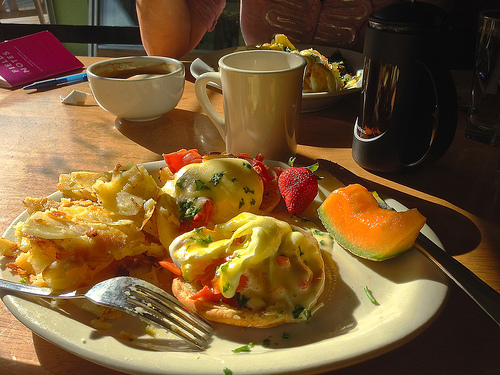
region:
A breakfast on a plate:
[19, 129, 439, 344]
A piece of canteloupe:
[321, 184, 429, 259]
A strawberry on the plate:
[277, 161, 319, 216]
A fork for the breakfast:
[9, 269, 214, 356]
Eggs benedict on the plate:
[177, 225, 339, 330]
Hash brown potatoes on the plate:
[20, 164, 161, 269]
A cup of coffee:
[197, 40, 312, 154]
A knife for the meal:
[391, 165, 498, 297]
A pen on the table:
[24, 63, 86, 90]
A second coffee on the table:
[79, 33, 189, 127]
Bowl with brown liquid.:
[89, 51, 191, 133]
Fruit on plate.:
[261, 163, 422, 270]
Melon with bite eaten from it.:
[344, 178, 417, 238]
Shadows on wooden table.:
[7, 84, 171, 207]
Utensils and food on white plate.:
[1, 154, 498, 333]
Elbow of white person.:
[135, 3, 218, 69]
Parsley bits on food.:
[177, 167, 280, 224]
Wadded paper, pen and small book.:
[2, 41, 96, 119]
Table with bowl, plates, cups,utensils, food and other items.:
[0, 45, 490, 370]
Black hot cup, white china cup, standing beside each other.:
[202, 49, 467, 188]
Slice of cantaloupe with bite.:
[319, 183, 416, 268]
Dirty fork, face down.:
[4, 269, 231, 367]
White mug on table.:
[196, 46, 323, 162]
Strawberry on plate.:
[278, 163, 325, 222]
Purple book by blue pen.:
[0, 29, 92, 97]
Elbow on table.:
[136, 1, 233, 70]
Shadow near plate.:
[1, 306, 136, 373]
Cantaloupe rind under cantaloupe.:
[319, 232, 406, 267]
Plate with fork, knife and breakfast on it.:
[12, 155, 432, 368]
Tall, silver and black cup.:
[345, 14, 453, 174]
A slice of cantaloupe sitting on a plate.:
[316, 167, 426, 261]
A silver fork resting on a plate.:
[0, 275, 216, 353]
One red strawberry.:
[276, 155, 326, 217]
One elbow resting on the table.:
[126, 17, 200, 64]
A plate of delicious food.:
[3, 142, 450, 367]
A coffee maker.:
[358, 10, 478, 196]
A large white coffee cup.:
[194, 48, 314, 163]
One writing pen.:
[15, 75, 104, 92]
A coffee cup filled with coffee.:
[83, 51, 192, 127]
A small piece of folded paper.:
[58, 83, 91, 107]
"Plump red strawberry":
[276, 165, 317, 215]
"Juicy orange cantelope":
[320, 182, 430, 259]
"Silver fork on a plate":
[5, 272, 211, 354]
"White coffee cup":
[195, 45, 315, 160]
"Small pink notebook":
[0, 22, 85, 87]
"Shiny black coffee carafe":
[345, 0, 465, 180]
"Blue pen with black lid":
[25, 60, 95, 91]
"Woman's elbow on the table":
[127, 0, 227, 64]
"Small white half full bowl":
[80, 50, 185, 120]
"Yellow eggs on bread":
[165, 215, 346, 330]